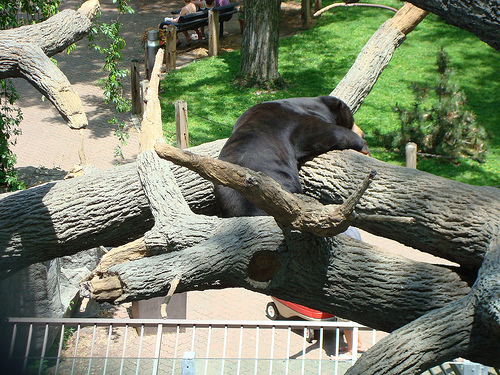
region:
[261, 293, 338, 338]
A toy red and beige wagon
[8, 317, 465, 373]
A fence keeping the black bear in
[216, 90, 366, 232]
A lazy, sleepy black bear in a tree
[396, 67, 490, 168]
A stubby green pine tree on the right side of the photo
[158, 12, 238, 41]
A bench for people to sit on made out of wood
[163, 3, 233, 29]
People sitting on the wooden bench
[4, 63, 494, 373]
Giant fake logs for the bear to play on and take a nap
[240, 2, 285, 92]
The trunk of a real tree near the bench, in the middle of the photo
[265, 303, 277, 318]
The black and white back wheel of the wagon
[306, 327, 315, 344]
The front right wheel of the wagon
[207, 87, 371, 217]
a sleeping bear in a tree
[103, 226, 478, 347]
a limb of a tree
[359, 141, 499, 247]
a limb of a tree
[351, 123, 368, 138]
the nose of a bear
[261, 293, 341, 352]
a child's toy on the pavement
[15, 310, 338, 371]
the railings of a fence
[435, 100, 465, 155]
the leaves of a tree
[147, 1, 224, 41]
a person sitting on a benh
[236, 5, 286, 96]
the trunk of a tree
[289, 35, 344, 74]
shadows on the ground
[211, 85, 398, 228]
bear in a tree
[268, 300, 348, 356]
red and brown wagon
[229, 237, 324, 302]
hole in tree trunk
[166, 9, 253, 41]
bench at the zoo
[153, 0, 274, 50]
people sitting on bench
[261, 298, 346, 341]
wagon is red and brown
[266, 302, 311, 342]
wheels are black and white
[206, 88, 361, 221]
bear's fur is black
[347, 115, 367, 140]
bear's nose is brown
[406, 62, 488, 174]
bush on the ground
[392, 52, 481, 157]
a little green tree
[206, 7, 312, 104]
a big tree trunk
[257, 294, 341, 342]
a little red wagon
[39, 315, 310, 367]
a whit railed fence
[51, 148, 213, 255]
a very big tree branch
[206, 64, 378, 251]
a black animal on a tree branch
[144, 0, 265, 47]
people sitting on a bench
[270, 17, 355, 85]
a patch of green grass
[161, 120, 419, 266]
a twisted tree branch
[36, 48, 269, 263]
a tree branch with no leaves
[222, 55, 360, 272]
bear sleeping on the tree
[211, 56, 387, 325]
the bear is black